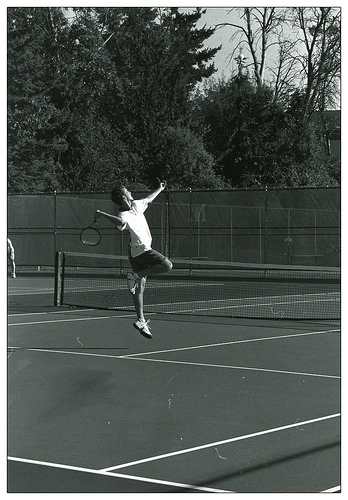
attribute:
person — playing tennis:
[92, 178, 174, 339]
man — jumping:
[76, 169, 200, 345]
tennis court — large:
[177, 321, 252, 375]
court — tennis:
[15, 232, 347, 487]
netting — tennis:
[60, 252, 339, 321]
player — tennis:
[75, 173, 195, 345]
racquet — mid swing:
[72, 204, 120, 263]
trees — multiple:
[6, 6, 340, 191]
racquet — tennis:
[79, 213, 101, 243]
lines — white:
[75, 308, 279, 499]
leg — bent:
[139, 254, 187, 285]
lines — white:
[71, 318, 289, 493]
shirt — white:
[106, 204, 177, 263]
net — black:
[54, 251, 342, 319]